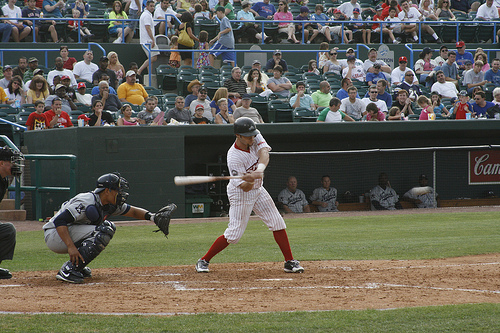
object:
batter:
[172, 116, 304, 273]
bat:
[174, 175, 242, 185]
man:
[116, 69, 149, 106]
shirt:
[117, 82, 148, 106]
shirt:
[289, 93, 314, 111]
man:
[311, 80, 333, 107]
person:
[107, 0, 128, 36]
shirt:
[108, 11, 129, 29]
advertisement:
[466, 144, 500, 186]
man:
[42, 171, 178, 284]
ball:
[410, 186, 428, 194]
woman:
[273, 1, 299, 44]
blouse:
[273, 11, 294, 27]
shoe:
[283, 260, 304, 273]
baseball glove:
[154, 203, 177, 235]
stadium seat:
[267, 100, 294, 123]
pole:
[285, 50, 319, 53]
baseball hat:
[234, 117, 259, 137]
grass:
[418, 232, 445, 249]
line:
[331, 286, 365, 289]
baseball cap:
[125, 70, 135, 77]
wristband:
[253, 163, 266, 172]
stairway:
[0, 198, 26, 221]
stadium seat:
[292, 107, 317, 123]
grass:
[429, 315, 440, 327]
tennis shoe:
[56, 260, 92, 283]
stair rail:
[10, 139, 79, 220]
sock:
[273, 229, 294, 263]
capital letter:
[474, 154, 489, 176]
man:
[193, 116, 304, 273]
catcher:
[41, 173, 175, 284]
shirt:
[90, 94, 123, 112]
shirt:
[311, 90, 333, 107]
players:
[308, 175, 340, 212]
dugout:
[347, 157, 382, 175]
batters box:
[225, 277, 258, 293]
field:
[451, 306, 498, 331]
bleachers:
[20, 118, 500, 219]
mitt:
[153, 203, 177, 235]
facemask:
[116, 176, 130, 205]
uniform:
[223, 128, 285, 244]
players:
[371, 173, 403, 211]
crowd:
[0, 0, 500, 128]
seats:
[154, 64, 368, 122]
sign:
[467, 150, 500, 184]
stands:
[0, 17, 500, 69]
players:
[278, 176, 311, 214]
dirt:
[0, 274, 500, 304]